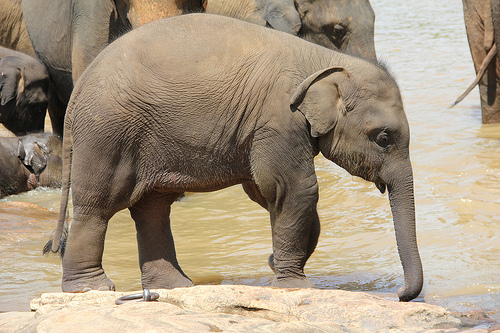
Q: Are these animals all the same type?
A: Yes, all the animals are elephants.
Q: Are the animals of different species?
A: No, all the animals are elephants.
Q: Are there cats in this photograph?
A: No, there are no cats.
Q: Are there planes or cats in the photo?
A: No, there are no cats or planes.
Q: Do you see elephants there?
A: Yes, there is an elephant.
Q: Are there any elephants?
A: Yes, there is an elephant.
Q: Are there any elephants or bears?
A: Yes, there is an elephant.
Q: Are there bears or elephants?
A: Yes, there is an elephant.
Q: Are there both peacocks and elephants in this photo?
A: No, there is an elephant but no peacocks.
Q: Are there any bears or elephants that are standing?
A: Yes, the elephant is standing.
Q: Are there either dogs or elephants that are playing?
A: Yes, the elephant is playing.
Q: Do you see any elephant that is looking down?
A: Yes, there is an elephant that is looking down.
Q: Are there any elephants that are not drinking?
A: Yes, there is an elephant that is looking down.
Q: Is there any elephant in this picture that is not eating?
A: Yes, there is an elephant that is playing.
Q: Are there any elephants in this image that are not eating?
A: Yes, there is an elephant that is playing.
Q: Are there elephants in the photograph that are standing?
A: Yes, there is an elephant that is standing.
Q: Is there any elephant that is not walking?
A: Yes, there is an elephant that is standing.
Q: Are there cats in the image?
A: No, there are no cats.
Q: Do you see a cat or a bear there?
A: No, there are no cats or bears.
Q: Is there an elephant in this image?
A: Yes, there is an elephant.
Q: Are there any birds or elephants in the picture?
A: Yes, there is an elephant.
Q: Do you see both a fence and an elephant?
A: No, there is an elephant but no fences.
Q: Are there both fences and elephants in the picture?
A: No, there is an elephant but no fences.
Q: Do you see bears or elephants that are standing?
A: Yes, the elephant is standing.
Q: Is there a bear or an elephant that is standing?
A: Yes, the elephant is standing.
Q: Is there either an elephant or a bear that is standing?
A: Yes, the elephant is standing.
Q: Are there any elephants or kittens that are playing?
A: Yes, the elephant is playing.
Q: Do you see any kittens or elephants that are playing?
A: Yes, the elephant is playing.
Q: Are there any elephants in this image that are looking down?
A: Yes, there is an elephant that is looking down.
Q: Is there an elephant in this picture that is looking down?
A: Yes, there is an elephant that is looking down.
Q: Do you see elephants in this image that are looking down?
A: Yes, there is an elephant that is looking down.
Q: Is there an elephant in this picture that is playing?
A: Yes, there is an elephant that is playing.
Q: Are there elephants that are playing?
A: Yes, there is an elephant that is playing.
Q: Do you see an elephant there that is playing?
A: Yes, there is an elephant that is playing.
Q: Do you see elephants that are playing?
A: Yes, there is an elephant that is playing.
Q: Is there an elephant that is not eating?
A: Yes, there is an elephant that is playing.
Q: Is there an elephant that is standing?
A: Yes, there is an elephant that is standing.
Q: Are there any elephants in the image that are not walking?
A: Yes, there is an elephant that is standing.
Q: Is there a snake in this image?
A: No, there are no snakes.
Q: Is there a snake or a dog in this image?
A: No, there are no snakes or dogs.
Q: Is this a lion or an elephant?
A: This is an elephant.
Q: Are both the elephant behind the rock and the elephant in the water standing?
A: Yes, both the elephant and the elephant are standing.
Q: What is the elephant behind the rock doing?
A: The elephant is standing.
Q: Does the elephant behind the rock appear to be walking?
A: No, the elephant is standing.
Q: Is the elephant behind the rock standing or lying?
A: The elephant is standing.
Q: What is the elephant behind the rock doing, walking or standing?
A: The elephant is standing.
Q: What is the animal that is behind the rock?
A: The animal is an elephant.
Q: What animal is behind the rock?
A: The animal is an elephant.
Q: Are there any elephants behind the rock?
A: Yes, there is an elephant behind the rock.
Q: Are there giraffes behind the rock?
A: No, there is an elephant behind the rock.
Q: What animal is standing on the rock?
A: The elephant is standing on the rock.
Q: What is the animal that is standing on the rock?
A: The animal is an elephant.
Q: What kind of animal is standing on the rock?
A: The animal is an elephant.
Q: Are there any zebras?
A: No, there are no zebras.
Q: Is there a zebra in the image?
A: No, there are no zebras.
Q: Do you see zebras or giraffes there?
A: No, there are no zebras or giraffes.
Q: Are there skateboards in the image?
A: No, there are no skateboards.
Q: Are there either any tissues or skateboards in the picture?
A: No, there are no skateboards or tissues.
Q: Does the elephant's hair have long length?
A: No, the hair is short.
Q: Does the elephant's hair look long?
A: No, the hair is short.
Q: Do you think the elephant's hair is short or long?
A: The hair is short.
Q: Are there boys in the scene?
A: No, there are no boys.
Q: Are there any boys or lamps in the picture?
A: No, there are no boys or lamps.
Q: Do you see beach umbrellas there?
A: No, there are no beach umbrellas.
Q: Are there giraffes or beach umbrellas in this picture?
A: No, there are no beach umbrellas or giraffes.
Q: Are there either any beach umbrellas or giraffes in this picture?
A: No, there are no beach umbrellas or giraffes.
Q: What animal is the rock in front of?
A: The rock is in front of the elephant.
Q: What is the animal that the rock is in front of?
A: The animal is an elephant.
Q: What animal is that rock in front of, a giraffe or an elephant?
A: The rock is in front of an elephant.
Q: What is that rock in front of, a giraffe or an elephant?
A: The rock is in front of an elephant.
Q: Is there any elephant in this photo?
A: Yes, there is an elephant.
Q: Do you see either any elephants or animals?
A: Yes, there is an elephant.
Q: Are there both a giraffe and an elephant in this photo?
A: No, there is an elephant but no giraffes.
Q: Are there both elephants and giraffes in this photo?
A: No, there is an elephant but no giraffes.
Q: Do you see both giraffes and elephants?
A: No, there is an elephant but no giraffes.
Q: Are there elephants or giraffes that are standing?
A: Yes, the elephant is standing.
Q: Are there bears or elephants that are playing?
A: Yes, the elephant is playing.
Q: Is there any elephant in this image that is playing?
A: Yes, there is an elephant that is playing.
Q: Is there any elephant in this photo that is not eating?
A: Yes, there is an elephant that is playing.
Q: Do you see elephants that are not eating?
A: Yes, there is an elephant that is playing .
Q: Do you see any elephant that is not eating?
A: Yes, there is an elephant that is playing .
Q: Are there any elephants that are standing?
A: Yes, there is an elephant that is standing.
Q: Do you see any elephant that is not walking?
A: Yes, there is an elephant that is standing .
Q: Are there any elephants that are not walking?
A: Yes, there is an elephant that is standing.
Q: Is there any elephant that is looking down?
A: Yes, there is an elephant that is looking down.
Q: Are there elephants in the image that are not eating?
A: Yes, there is an elephant that is looking down.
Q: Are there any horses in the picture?
A: No, there are no horses.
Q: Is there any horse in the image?
A: No, there are no horses.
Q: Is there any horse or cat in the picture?
A: No, there are no horses or cats.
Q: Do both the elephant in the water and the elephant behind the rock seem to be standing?
A: Yes, both the elephant and the elephant are standing.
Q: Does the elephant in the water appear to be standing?
A: Yes, the elephant is standing.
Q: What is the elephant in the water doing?
A: The elephant is standing.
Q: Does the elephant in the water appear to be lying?
A: No, the elephant is standing.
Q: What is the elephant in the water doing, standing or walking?
A: The elephant is standing.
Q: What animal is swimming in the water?
A: The animal is an elephant.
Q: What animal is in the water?
A: The elephant is in the water.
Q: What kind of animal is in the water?
A: The animal is an elephant.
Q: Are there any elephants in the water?
A: Yes, there is an elephant in the water.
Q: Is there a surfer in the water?
A: No, there is an elephant in the water.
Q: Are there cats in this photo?
A: No, there are no cats.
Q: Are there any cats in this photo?
A: No, there are no cats.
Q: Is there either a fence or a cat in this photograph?
A: No, there are no cats or fences.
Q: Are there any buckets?
A: No, there are no buckets.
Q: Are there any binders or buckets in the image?
A: No, there are no buckets or binders.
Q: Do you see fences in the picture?
A: No, there are no fences.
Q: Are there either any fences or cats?
A: No, there are no fences or cats.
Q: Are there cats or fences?
A: No, there are no fences or cats.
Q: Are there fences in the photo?
A: No, there are no fences.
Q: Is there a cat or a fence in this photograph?
A: No, there are no fences or cats.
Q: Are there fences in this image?
A: No, there are no fences.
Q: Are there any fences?
A: No, there are no fences.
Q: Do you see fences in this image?
A: No, there are no fences.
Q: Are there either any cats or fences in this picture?
A: No, there are no fences or cats.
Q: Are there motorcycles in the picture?
A: No, there are no motorcycles.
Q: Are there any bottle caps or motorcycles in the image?
A: No, there are no motorcycles or bottle caps.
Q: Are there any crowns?
A: No, there are no crowns.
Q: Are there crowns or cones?
A: No, there are no crowns or cones.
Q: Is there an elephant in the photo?
A: Yes, there is an elephant.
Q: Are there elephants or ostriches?
A: Yes, there is an elephant.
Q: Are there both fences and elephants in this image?
A: No, there is an elephant but no fences.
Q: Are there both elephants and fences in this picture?
A: No, there is an elephant but no fences.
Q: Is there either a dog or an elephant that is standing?
A: Yes, the elephant is standing.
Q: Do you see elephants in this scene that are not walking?
A: Yes, there is an elephant that is standing .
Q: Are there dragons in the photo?
A: No, there are no dragons.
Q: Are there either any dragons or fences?
A: No, there are no dragons or fences.